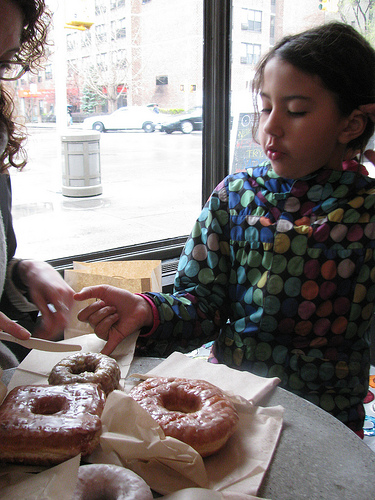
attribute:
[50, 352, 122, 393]
donut — freshly made, glazed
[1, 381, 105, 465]
donut — freshly made, glazed, large, square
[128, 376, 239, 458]
donut — freshly made, glazed, large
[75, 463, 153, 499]
donut — freshly made, glazed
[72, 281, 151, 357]
hand — pointing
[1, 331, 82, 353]
knife — plastic, white, being held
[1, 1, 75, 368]
adult — cutting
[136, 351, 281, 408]
napkin — brown, large, white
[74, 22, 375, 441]
girl — young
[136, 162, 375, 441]
blouse — many colored, polka-dot, colorful, colored with dots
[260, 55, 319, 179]
face — anticipating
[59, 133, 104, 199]
trash can — gray, public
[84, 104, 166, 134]
car — white, on street, large, non black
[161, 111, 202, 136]
car — black, on street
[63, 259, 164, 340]
paper bag — brown, for donuts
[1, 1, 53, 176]
hair — curly, dark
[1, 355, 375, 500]
table — round, gray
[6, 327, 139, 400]
napkin — large, white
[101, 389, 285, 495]
napkin — large, white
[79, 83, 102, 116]
tree — small, green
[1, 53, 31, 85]
eyeglasses — worn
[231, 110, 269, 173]
advertising board — partially visible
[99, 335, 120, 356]
finger — little